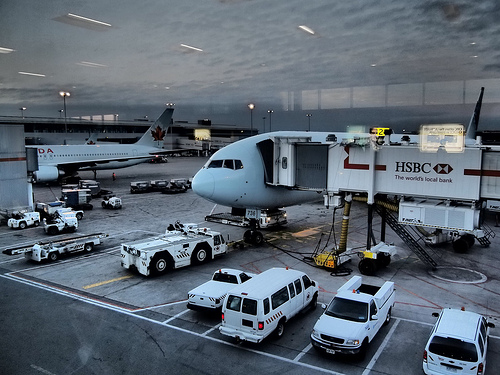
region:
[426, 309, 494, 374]
white van is parked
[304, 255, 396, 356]
truck is parked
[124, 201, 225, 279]
luggage carrier near airplane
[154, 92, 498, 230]
airplane is unloading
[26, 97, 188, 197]
white airplane is parked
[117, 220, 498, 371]
white vehicles are parked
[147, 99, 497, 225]
white airplane is unloading passengers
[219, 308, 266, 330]
red lights on back of van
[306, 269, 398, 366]
white truck is parked in parking lot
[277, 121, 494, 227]
unloading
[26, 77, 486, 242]
Two planes at an airport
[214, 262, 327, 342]
A white commercial van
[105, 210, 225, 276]
Vehicle that pushes the plane around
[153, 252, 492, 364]
White vehicles parked in a row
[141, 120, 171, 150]
A red maple leaf on the tail of a plane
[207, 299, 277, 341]
The van has its brakes on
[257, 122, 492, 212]
This how people board the plane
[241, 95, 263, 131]
Lights on the tarmac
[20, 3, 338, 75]
Strange streaks of light in the sky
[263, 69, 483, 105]
Lights from the airport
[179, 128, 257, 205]
nose of the plane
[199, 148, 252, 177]
window on the plane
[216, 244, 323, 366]
van on the ground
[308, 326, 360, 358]
front of the truck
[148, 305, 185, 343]
white lines on the ground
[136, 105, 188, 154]
tail of a plane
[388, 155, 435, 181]
letters on terminal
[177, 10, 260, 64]
sky above the planes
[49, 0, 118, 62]
reflection in a window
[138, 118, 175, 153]
leaf on the tail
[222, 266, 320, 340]
white van in parking space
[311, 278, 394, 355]
white pick up truck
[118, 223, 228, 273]
work truck by plane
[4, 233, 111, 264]
trailor on wheels in parking space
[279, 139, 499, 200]
plane loader on posts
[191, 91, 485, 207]
white plane in air port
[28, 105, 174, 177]
white and grey plane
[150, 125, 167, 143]
red maple leaf on plane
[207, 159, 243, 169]
glass cockpit windows on plane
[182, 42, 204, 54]
tube light on ceiling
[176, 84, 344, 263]
This is an airplane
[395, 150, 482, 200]
This says HSBC in black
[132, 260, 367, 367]
These are cars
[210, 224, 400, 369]
The cars are parked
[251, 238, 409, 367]
The cars are white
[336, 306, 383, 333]
This is a window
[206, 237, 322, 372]
This is a van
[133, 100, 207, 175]
This is a red leaf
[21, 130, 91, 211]
This is air canada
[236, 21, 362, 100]
These are cloudy skies